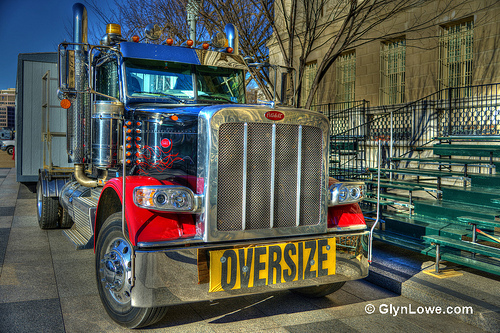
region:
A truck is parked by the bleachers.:
[40, 50, 365, 305]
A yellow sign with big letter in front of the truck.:
[187, 236, 339, 302]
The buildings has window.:
[330, 45, 476, 100]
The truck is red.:
[101, 143, 188, 241]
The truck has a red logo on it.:
[245, 105, 295, 125]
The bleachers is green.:
[412, 165, 488, 245]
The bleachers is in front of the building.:
[360, 97, 494, 245]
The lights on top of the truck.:
[127, 27, 236, 56]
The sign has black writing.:
[223, 249, 320, 274]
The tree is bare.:
[238, 8, 346, 98]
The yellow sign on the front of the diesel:
[206, 235, 338, 293]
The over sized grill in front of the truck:
[198, 103, 332, 241]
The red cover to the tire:
[84, 175, 191, 237]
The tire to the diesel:
[93, 211, 178, 328]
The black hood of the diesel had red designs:
[122, 104, 198, 174]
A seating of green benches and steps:
[395, 127, 494, 273]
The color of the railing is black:
[331, 85, 498, 135]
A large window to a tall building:
[370, 27, 416, 106]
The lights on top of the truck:
[123, 30, 239, 55]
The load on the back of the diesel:
[10, 40, 66, 184]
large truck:
[9, 6, 443, 331]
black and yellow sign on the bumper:
[204, 237, 358, 298]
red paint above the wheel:
[82, 173, 196, 327]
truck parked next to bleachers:
[16, 12, 496, 324]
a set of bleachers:
[335, 81, 499, 271]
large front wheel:
[79, 203, 169, 329]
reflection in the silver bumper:
[130, 245, 212, 307]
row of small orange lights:
[124, 23, 238, 55]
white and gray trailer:
[12, 31, 99, 216]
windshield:
[127, 62, 250, 115]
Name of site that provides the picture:
[373, 298, 479, 330]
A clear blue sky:
[16, 13, 39, 30]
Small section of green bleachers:
[416, 192, 460, 231]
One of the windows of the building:
[377, 36, 413, 107]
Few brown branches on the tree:
[154, 8, 179, 25]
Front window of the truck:
[140, 68, 259, 100]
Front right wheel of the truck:
[93, 210, 150, 320]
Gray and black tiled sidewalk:
[13, 262, 75, 319]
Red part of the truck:
[156, 220, 172, 235]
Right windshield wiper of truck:
[139, 90, 178, 105]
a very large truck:
[8, 6, 390, 328]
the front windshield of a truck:
[113, 47, 255, 122]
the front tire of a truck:
[86, 211, 163, 327]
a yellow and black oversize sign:
[198, 234, 352, 292]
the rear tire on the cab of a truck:
[29, 166, 72, 233]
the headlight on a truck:
[130, 180, 203, 218]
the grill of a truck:
[204, 105, 330, 232]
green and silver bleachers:
[359, 80, 499, 308]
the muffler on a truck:
[56, 1, 111, 193]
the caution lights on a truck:
[128, 30, 236, 61]